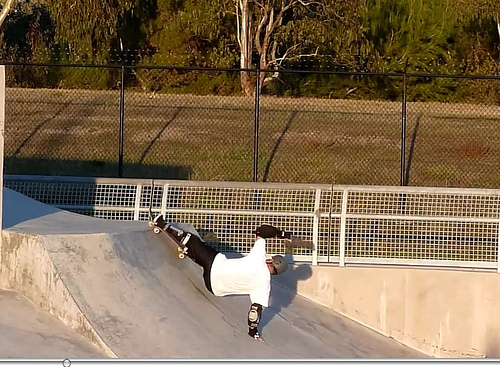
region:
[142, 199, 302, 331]
A man doing skate tricks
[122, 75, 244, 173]
A black wire mesh fence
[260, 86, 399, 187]
A black wire mesh fence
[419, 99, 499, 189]
A black wire mesh fence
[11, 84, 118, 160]
A black wire mesh fence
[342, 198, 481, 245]
A white wire mesh fence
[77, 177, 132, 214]
A white wire mesh fence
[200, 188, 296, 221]
A white wire mesh fence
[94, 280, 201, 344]
A sliding brown skate ground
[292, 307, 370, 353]
A sliding brown skate ground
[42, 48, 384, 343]
this man is skating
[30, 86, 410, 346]
this is at a park for skateboarding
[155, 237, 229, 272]
the man is wearing black pants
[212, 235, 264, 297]
the man has a white shirt on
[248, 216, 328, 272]
the man has arm pads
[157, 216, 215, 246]
the man has knee pads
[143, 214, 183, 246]
the skateboard deck is dark gray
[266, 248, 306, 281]
the man has a helmet on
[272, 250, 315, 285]
the helmet is gray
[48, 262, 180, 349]
the ramp is light gray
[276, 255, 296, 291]
This man is wearing a very hard helmet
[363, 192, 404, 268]
This fence is white in the background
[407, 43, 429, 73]
There is a green tree that is in the distance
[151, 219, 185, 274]
There is a skateboard that is visible here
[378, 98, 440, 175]
There is a black fence that is visible here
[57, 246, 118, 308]
There is an off-white ramp here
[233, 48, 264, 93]
There is a light brown trunk that is there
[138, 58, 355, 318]
Jackson Mingus took this photo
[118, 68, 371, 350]
This photo was taken during the season of summer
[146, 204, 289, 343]
a man is on a skateboard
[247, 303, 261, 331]
elbow pad on a man's arm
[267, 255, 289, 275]
a man is wearing a helmet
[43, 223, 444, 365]
ramp is made of concrete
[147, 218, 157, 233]
wheels on a skateboard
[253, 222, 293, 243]
a man's black arm band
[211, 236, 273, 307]
a man's white t-shirt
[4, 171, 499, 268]
a metal fence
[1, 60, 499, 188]
a black metal fence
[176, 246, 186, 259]
wheels on a skateboard